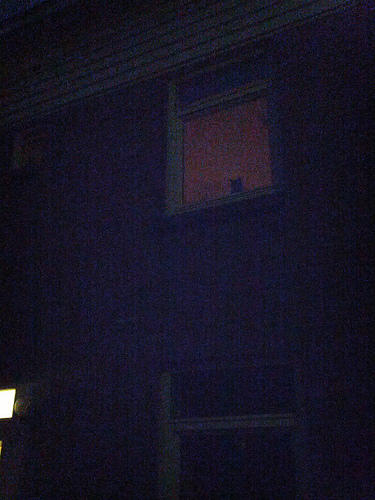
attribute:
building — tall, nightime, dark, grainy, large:
[2, 1, 375, 494]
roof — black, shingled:
[1, 0, 373, 124]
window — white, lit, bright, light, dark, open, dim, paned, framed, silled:
[173, 48, 281, 205]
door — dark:
[165, 359, 312, 499]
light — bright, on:
[0, 384, 19, 424]